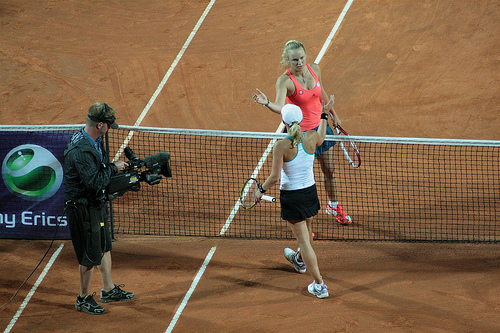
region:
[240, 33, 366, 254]
woman holding tennis racquet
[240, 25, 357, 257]
woman wearing melon color tank top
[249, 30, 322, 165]
woman with long blond hair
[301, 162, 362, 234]
woman wearing melon color tennis shoes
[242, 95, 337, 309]
woman wearing white ball cap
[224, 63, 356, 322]
woman wearing white tank top with blue trim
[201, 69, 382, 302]
woman wearing black skirt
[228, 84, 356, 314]
woman wearing white tennis shoes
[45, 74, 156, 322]
man wearing black visor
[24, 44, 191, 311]
man holding large black camera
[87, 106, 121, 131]
a black visor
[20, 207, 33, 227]
a capital white letter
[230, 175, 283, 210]
a white and green racket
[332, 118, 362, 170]
a red and white racket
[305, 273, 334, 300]
a woman's tennis shoe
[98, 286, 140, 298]
a man's tennis shoe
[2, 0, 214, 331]
a long white line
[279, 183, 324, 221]
a short black skirt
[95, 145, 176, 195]
a big black video camera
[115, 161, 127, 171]
the hand of a man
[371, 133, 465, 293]
the net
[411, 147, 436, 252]
the net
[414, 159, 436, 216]
the net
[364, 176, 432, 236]
the net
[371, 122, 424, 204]
the net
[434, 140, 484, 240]
the net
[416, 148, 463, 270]
the net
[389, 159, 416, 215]
the net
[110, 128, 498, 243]
a big net in the ground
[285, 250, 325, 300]
two shoes of a girl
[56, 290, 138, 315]
two shoes of a man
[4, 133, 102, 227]
a small display on net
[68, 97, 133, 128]
a cap on the man head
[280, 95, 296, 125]
a small cap on women head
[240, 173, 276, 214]
shuttle bat holding by women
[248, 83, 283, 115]
the hand of a women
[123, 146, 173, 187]
an object holding by man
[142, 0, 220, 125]
a line drawn on ground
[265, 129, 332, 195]
the white colored t shirt of a tennis player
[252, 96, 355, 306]
the tennis player clapping hand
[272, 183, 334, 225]
the black color skirt of a tennis player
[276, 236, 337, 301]
the white color shoes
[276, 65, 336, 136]
the pink color t shirt of a tennis player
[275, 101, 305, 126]
the white color cap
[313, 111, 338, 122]
the black colored wrist band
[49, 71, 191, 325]
the camera man shooting two players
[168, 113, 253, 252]
the net used in tennis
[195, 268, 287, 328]
the brown colored tennis ground